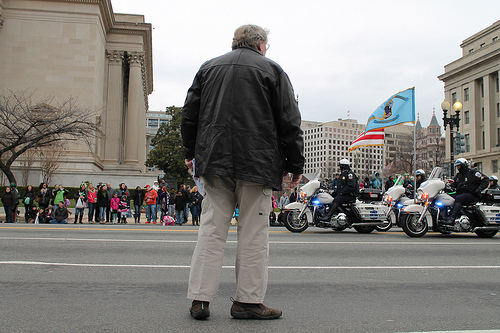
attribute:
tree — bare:
[2, 94, 84, 231]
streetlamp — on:
[439, 99, 465, 129]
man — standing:
[184, 25, 302, 319]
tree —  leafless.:
[0, 87, 108, 211]